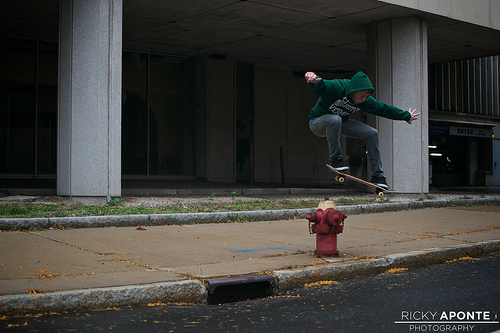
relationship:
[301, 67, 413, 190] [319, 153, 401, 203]
boy jumping with skateboard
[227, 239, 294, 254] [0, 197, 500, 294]
paint on sidewalk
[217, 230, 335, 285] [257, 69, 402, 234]
line on sidewalk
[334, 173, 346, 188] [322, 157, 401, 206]
wheel on skateboard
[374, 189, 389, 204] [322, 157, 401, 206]
wheel on skateboard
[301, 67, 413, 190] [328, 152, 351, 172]
boy has a shoe